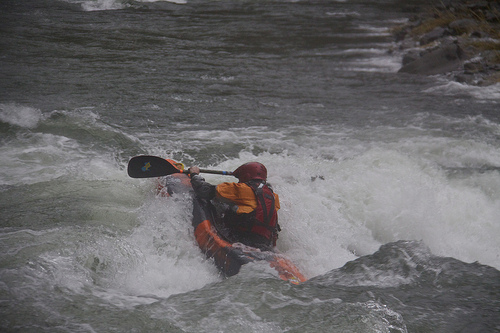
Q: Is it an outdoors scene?
A: Yes, it is outdoors.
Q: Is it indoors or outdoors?
A: It is outdoors.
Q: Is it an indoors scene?
A: No, it is outdoors.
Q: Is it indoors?
A: No, it is outdoors.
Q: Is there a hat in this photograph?
A: Yes, there is a hat.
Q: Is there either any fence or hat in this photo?
A: Yes, there is a hat.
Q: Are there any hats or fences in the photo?
A: Yes, there is a hat.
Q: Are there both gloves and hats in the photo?
A: No, there is a hat but no gloves.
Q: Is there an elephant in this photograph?
A: No, there are no elephants.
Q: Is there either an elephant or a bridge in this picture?
A: No, there are no elephants or bridges.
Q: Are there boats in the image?
A: Yes, there is a boat.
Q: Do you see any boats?
A: Yes, there is a boat.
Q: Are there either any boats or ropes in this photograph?
A: Yes, there is a boat.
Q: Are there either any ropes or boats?
A: Yes, there is a boat.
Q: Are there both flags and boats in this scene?
A: No, there is a boat but no flags.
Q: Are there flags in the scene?
A: No, there are no flags.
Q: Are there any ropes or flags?
A: No, there are no flags or ropes.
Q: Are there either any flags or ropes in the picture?
A: No, there are no flags or ropes.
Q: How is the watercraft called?
A: The watercraft is a boat.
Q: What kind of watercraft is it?
A: The watercraft is a boat.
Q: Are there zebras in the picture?
A: No, there are no zebras.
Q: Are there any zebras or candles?
A: No, there are no zebras or candles.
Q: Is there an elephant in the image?
A: No, there are no elephants.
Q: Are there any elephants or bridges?
A: No, there are no elephants or bridges.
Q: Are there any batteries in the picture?
A: No, there are no batteries.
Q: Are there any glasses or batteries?
A: No, there are no batteries or glasses.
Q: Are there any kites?
A: No, there are no kites.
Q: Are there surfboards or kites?
A: No, there are no kites or surfboards.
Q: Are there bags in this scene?
A: No, there are no bags.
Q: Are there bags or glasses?
A: No, there are no bags or glasses.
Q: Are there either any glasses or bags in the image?
A: No, there are no bags or glasses.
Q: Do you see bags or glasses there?
A: No, there are no bags or glasses.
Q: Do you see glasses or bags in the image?
A: No, there are no bags or glasses.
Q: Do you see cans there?
A: No, there are no cans.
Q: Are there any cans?
A: No, there are no cans.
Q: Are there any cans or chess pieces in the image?
A: No, there are no cans or chess pieces.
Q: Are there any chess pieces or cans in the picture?
A: No, there are no cans or chess pieces.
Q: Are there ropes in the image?
A: No, there are no ropes.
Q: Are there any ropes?
A: No, there are no ropes.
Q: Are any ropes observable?
A: No, there are no ropes.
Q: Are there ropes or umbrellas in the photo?
A: No, there are no ropes or umbrellas.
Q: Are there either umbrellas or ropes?
A: No, there are no ropes or umbrellas.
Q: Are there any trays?
A: No, there are no trays.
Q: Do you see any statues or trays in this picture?
A: No, there are no trays or statues.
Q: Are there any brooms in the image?
A: No, there are no brooms.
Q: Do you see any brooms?
A: No, there are no brooms.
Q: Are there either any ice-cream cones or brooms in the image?
A: No, there are no brooms or ice-cream cones.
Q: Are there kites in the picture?
A: No, there are no kites.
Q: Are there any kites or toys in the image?
A: No, there are no kites or toys.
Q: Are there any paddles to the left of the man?
A: Yes, there is a paddle to the left of the man.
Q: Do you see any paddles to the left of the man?
A: Yes, there is a paddle to the left of the man.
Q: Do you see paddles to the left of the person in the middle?
A: Yes, there is a paddle to the left of the man.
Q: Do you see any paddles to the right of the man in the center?
A: No, the paddle is to the left of the man.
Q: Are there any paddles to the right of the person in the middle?
A: No, the paddle is to the left of the man.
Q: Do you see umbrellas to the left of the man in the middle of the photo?
A: No, there is a paddle to the left of the man.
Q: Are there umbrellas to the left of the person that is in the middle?
A: No, there is a paddle to the left of the man.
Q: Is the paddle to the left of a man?
A: Yes, the paddle is to the left of a man.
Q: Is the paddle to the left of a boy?
A: No, the paddle is to the left of a man.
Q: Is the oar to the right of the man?
A: No, the oar is to the left of the man.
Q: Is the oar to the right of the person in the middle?
A: No, the oar is to the left of the man.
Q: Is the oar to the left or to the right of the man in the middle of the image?
A: The oar is to the left of the man.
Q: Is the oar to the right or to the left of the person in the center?
A: The oar is to the left of the man.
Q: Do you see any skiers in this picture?
A: No, there are no skiers.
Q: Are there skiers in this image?
A: No, there are no skiers.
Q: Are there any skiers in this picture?
A: No, there are no skiers.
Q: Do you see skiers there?
A: No, there are no skiers.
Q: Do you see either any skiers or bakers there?
A: No, there are no skiers or bakers.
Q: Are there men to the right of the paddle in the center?
A: Yes, there is a man to the right of the oar.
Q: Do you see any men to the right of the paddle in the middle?
A: Yes, there is a man to the right of the oar.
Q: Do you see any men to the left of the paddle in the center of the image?
A: No, the man is to the right of the oar.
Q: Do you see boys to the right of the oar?
A: No, there is a man to the right of the oar.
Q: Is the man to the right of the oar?
A: Yes, the man is to the right of the oar.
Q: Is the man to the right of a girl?
A: No, the man is to the right of the oar.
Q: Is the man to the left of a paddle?
A: No, the man is to the right of a paddle.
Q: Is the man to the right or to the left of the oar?
A: The man is to the right of the oar.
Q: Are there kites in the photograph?
A: No, there are no kites.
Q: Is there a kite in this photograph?
A: No, there are no kites.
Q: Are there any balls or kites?
A: No, there are no kites or balls.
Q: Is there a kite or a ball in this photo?
A: No, there are no kites or balls.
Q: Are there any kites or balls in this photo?
A: No, there are no kites or balls.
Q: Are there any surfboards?
A: No, there are no surfboards.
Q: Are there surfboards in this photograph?
A: No, there are no surfboards.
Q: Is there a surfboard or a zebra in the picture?
A: No, there are no surfboards or zebras.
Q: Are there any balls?
A: No, there are no balls.